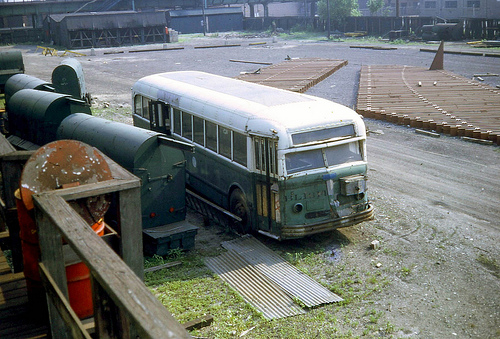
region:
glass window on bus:
[231, 130, 245, 165]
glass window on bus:
[216, 123, 231, 160]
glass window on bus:
[206, 119, 217, 152]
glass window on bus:
[193, 113, 205, 147]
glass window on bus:
[181, 111, 191, 138]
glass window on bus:
[171, 106, 182, 136]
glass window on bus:
[133, 91, 141, 115]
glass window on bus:
[141, 96, 151, 118]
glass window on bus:
[286, 148, 322, 173]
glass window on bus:
[323, 138, 363, 160]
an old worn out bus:
[112, 44, 358, 266]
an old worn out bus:
[132, 34, 404, 302]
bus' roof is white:
[134, 68, 358, 200]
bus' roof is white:
[122, 46, 374, 190]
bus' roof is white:
[134, 49, 366, 187]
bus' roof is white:
[127, 52, 369, 177]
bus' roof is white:
[103, 44, 392, 167]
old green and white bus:
[132, 69, 376, 238]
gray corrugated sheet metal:
[201, 233, 343, 321]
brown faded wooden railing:
[1, 133, 195, 338]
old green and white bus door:
[251, 135, 281, 234]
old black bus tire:
[227, 188, 252, 232]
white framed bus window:
[230, 128, 249, 169]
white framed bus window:
[215, 122, 233, 160]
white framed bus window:
[204, 119, 219, 152]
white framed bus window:
[280, 137, 365, 173]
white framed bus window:
[170, 106, 184, 138]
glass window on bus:
[171, 108, 181, 133]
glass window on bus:
[133, 92, 143, 114]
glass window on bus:
[327, 140, 360, 165]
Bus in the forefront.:
[120, 52, 370, 253]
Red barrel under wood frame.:
[56, 229, 102, 323]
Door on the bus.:
[247, 127, 285, 229]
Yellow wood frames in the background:
[28, 38, 83, 58]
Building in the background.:
[163, 2, 251, 39]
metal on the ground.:
[194, 229, 351, 324]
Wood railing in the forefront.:
[0, 125, 200, 333]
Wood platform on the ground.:
[352, 50, 497, 153]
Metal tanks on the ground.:
[0, 53, 197, 234]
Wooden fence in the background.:
[239, 5, 498, 40]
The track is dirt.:
[411, 160, 474, 215]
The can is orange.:
[8, 196, 113, 323]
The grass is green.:
[160, 268, 211, 316]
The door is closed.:
[242, 137, 289, 249]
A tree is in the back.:
[314, 6, 357, 41]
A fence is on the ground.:
[210, 242, 320, 332]